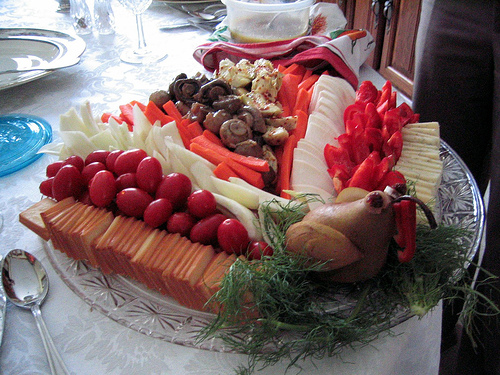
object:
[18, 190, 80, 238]
cheese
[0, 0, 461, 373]
table cloth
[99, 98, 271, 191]
carrots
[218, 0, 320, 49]
bowl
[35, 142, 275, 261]
olives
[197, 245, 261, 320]
cheese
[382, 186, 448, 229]
cheese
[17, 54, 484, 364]
platter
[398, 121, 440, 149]
cheese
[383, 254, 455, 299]
dill herb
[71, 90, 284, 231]
sliced vegetables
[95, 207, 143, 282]
cheese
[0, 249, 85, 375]
silver spoon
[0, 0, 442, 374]
table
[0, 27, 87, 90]
plate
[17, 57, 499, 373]
food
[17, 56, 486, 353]
foodplatter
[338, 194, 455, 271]
plate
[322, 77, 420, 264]
red peppers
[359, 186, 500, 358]
garnish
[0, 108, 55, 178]
blue lid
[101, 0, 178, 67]
glass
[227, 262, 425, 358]
garnish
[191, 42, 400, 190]
veggies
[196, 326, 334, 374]
dill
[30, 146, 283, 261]
tomatoes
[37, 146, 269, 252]
pile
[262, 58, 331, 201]
raw carrots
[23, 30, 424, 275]
food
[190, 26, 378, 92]
cloth